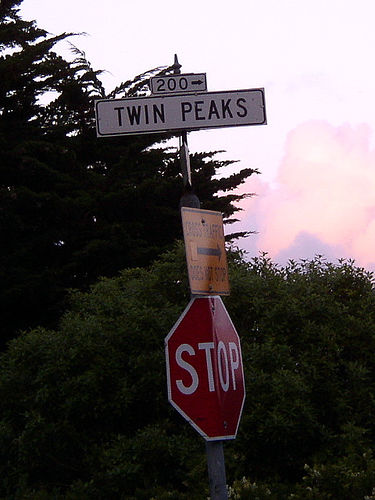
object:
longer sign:
[94, 87, 266, 138]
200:
[157, 76, 188, 92]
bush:
[0, 247, 375, 500]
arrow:
[192, 79, 203, 84]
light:
[267, 177, 374, 262]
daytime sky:
[44, 1, 373, 267]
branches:
[0, 30, 146, 96]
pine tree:
[0, 0, 258, 340]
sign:
[96, 87, 265, 138]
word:
[113, 104, 165, 128]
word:
[181, 98, 248, 121]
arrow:
[198, 244, 222, 262]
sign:
[180, 205, 230, 297]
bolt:
[201, 218, 205, 223]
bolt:
[209, 283, 213, 289]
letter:
[114, 98, 247, 126]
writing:
[176, 341, 239, 394]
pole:
[169, 53, 228, 500]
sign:
[150, 71, 207, 96]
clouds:
[246, 96, 375, 257]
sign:
[152, 289, 272, 442]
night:
[0, 0, 375, 500]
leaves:
[99, 302, 133, 340]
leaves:
[309, 392, 352, 415]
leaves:
[319, 275, 353, 317]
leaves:
[276, 300, 316, 335]